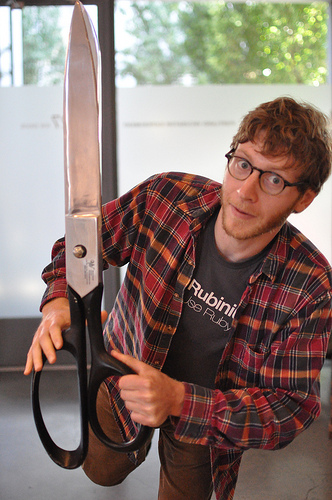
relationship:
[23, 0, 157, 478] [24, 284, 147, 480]
scissors has handle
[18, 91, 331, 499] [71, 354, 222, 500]
dude wears pants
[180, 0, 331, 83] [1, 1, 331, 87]
tree through window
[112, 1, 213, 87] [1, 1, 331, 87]
tree through window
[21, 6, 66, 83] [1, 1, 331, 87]
tree through window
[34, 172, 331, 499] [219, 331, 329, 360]
plaid has red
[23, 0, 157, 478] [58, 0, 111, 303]
scissors has blades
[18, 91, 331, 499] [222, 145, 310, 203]
dude wears frames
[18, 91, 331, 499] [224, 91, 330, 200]
dude has hair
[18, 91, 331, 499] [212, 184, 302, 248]
dude has beard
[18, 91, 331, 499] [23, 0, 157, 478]
dude holds scissors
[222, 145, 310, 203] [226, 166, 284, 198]
frames have brown bottoms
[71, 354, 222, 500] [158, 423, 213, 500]
pants have wrinkles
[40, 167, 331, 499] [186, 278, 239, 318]
shirt says 'rubinius'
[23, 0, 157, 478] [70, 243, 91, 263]
scissors held together by screw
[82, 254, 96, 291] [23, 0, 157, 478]
writing on scissors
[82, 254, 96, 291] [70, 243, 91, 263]
writing beside screw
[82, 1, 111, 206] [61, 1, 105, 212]
bottom blade can be seen beneath top blade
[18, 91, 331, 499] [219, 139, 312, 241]
dude has face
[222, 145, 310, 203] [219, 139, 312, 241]
frames on face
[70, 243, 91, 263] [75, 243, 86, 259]
screw has shadow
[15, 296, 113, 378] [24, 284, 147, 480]
hand holds handle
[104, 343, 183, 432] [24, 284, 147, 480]
hand holds handle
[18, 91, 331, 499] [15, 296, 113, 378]
dude has hand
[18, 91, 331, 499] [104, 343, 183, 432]
dude has hand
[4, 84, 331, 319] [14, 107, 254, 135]
wall has writing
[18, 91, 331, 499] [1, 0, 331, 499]
dude probably in gallery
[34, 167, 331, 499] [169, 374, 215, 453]
shirt has cuff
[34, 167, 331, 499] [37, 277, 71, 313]
shirt has cuff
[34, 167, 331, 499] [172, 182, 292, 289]
shirt has collar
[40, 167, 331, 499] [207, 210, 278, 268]
shirt has collar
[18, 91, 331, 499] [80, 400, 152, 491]
dude has knee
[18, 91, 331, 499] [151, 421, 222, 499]
dude has leg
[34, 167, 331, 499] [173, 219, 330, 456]
shirt has sleeve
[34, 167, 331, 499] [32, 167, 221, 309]
shirt has sleeve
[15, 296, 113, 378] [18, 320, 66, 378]
hand has fingers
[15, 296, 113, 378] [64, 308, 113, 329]
hand has thumb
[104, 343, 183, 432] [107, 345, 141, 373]
hand has thumb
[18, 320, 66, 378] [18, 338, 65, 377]
fingers have fingernails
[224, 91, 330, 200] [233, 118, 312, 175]
hair has bangs